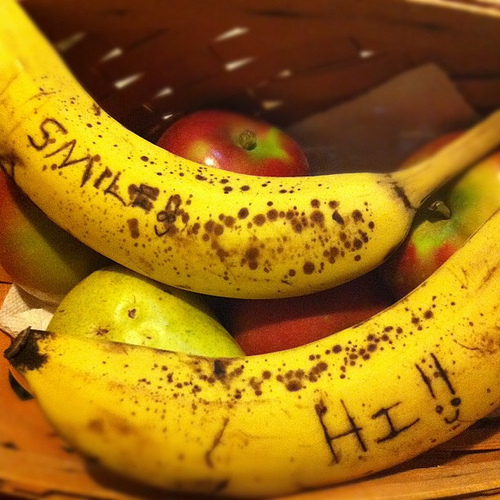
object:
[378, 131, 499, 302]
apple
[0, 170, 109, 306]
apple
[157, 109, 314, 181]
apple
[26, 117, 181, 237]
drawing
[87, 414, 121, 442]
dots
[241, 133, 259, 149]
stem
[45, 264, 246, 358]
fruit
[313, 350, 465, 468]
carving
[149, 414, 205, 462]
dots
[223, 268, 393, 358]
apple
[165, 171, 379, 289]
dot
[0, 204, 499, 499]
banana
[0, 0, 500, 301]
banana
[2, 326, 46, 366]
banana top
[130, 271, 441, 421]
dot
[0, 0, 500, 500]
basket